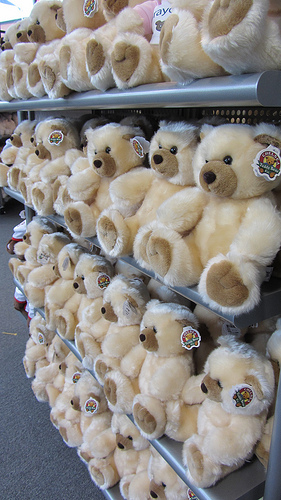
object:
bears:
[178, 330, 271, 482]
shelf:
[1, 74, 275, 114]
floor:
[1, 203, 120, 499]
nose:
[152, 148, 164, 166]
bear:
[254, 141, 281, 183]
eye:
[169, 143, 179, 159]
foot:
[145, 230, 177, 284]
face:
[146, 128, 194, 184]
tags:
[230, 382, 254, 407]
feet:
[203, 259, 249, 304]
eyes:
[222, 155, 233, 167]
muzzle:
[200, 161, 238, 200]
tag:
[252, 144, 281, 183]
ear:
[252, 120, 280, 147]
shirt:
[137, 0, 173, 43]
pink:
[134, 0, 155, 29]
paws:
[159, 195, 191, 233]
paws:
[238, 223, 265, 268]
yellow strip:
[3, 328, 18, 339]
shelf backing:
[145, 105, 281, 125]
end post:
[261, 361, 280, 500]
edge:
[255, 64, 280, 112]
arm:
[237, 195, 280, 266]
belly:
[188, 205, 241, 258]